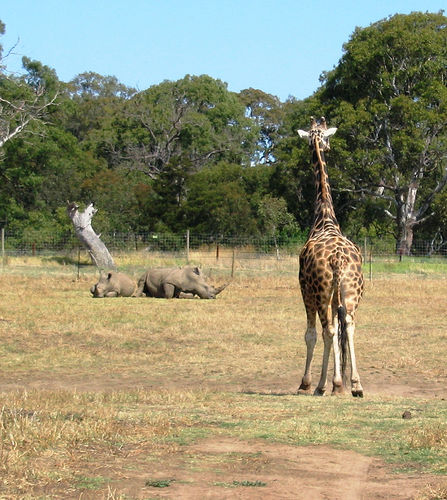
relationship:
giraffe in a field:
[288, 111, 376, 407] [128, 310, 416, 483]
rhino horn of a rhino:
[91, 283, 99, 297] [91, 269, 136, 297]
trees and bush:
[0, 56, 443, 248] [0, 218, 443, 253]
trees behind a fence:
[0, 56, 443, 248] [1, 227, 445, 256]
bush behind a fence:
[0, 218, 443, 253] [1, 227, 445, 256]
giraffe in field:
[288, 111, 376, 407] [5, 269, 437, 498]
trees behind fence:
[0, 56, 443, 248] [116, 215, 302, 278]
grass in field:
[109, 327, 428, 459] [236, 370, 404, 472]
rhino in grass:
[87, 264, 227, 304] [98, 291, 238, 317]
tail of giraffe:
[330, 249, 352, 386] [267, 102, 368, 338]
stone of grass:
[397, 399, 439, 429] [394, 414, 430, 428]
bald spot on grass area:
[114, 439, 445, 499] [1, 266, 445, 498]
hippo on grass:
[132, 265, 229, 299] [0, 242, 446, 498]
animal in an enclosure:
[294, 115, 367, 396] [109, 231, 300, 274]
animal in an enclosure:
[134, 265, 229, 299] [109, 231, 300, 274]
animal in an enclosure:
[88, 271, 142, 298] [109, 231, 300, 274]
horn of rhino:
[212, 278, 233, 301] [140, 266, 224, 303]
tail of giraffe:
[330, 249, 352, 386] [295, 113, 367, 398]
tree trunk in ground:
[70, 209, 118, 280] [5, 251, 434, 498]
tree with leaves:
[301, 12, 445, 252] [298, 19, 445, 199]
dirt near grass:
[31, 433, 446, 498] [0, 242, 446, 498]